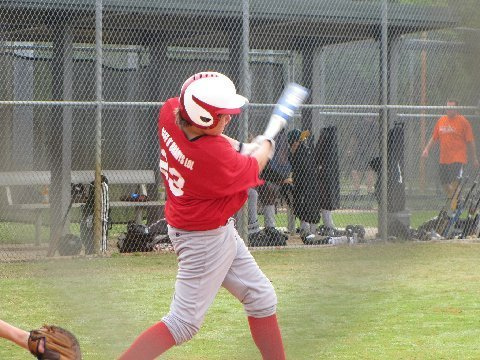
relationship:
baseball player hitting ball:
[93, 52, 328, 359] [463, 203, 479, 210]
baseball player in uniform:
[93, 52, 328, 359] [145, 103, 257, 232]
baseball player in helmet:
[93, 52, 328, 359] [149, 48, 251, 139]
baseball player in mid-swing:
[93, 52, 328, 359] [237, 58, 339, 200]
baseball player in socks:
[93, 52, 328, 359] [245, 311, 300, 359]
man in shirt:
[84, 53, 323, 356] [419, 105, 476, 168]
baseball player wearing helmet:
[93, 52, 328, 359] [149, 48, 251, 139]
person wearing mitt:
[1, 315, 28, 354] [29, 319, 76, 359]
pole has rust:
[90, 8, 109, 102] [91, 8, 106, 102]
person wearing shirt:
[1, 315, 28, 354] [419, 105, 476, 168]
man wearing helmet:
[84, 53, 323, 356] [149, 48, 251, 139]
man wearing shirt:
[84, 53, 323, 356] [419, 105, 476, 168]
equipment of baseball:
[288, 231, 372, 246] [298, 221, 365, 250]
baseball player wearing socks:
[93, 52, 328, 359] [245, 311, 300, 359]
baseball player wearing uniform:
[93, 52, 328, 359] [145, 103, 257, 232]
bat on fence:
[253, 70, 318, 145] [27, 28, 117, 116]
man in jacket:
[84, 53, 323, 356] [284, 150, 325, 223]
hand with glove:
[27, 315, 73, 359] [29, 319, 76, 359]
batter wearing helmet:
[128, 59, 295, 359] [149, 48, 251, 139]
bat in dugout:
[253, 70, 318, 145] [60, 18, 386, 82]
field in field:
[291, 233, 479, 360] [312, 257, 479, 317]